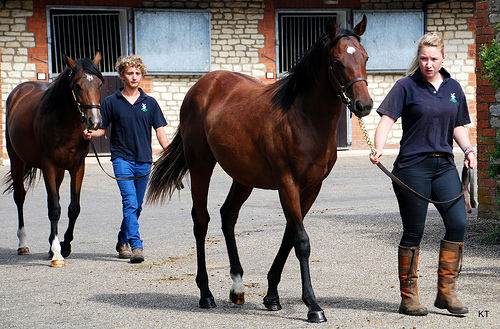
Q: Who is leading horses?
A: Two trainers.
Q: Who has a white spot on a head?
A: A horse.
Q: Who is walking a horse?
A: A girl.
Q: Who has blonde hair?
A: A boy.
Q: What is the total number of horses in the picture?
A: 2.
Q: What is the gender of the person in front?
A: Female.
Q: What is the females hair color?
A: Blond.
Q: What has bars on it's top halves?
A: The two doors.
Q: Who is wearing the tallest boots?
A: The female.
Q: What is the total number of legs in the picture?
A: 12.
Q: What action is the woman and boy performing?
A: Leading horses.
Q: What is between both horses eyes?
A: A white spot.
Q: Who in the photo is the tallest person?
A: The female.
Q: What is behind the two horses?
A: A brick building.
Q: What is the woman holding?
A: A lead for the horse.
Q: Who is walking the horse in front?
A: A woman.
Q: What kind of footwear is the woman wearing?
A: Boots.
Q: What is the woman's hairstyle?
A: It's in a ponytail.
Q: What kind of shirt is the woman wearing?
A: A polo shirt.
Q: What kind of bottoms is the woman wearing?
A: Pants.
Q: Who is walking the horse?
A: A young man.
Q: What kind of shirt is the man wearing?
A: A polo shirt.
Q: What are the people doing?
A: Leading.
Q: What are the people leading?
A: Horses.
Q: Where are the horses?
A: By the people.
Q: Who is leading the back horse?
A: The man.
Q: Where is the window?
A: On the building.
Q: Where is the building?
A: Behind the horse.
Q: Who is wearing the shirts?
A: The people.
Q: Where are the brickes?
A: In the buildin.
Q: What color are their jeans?
A: Blue.